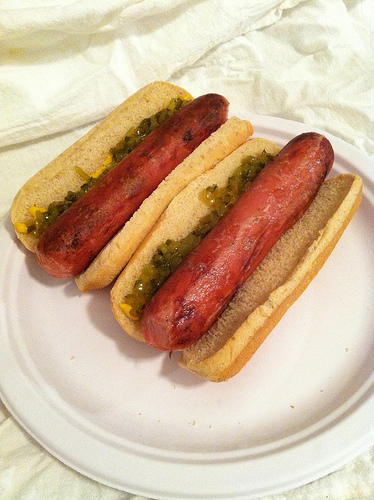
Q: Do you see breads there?
A: Yes, there is a bread.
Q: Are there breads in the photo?
A: Yes, there is a bread.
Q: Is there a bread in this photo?
A: Yes, there is a bread.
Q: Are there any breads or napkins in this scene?
A: Yes, there is a bread.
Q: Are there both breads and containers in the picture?
A: No, there is a bread but no containers.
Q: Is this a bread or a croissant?
A: This is a bread.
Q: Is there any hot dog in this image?
A: Yes, there is a hot dog.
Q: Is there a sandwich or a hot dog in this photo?
A: Yes, there is a hot dog.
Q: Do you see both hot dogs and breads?
A: Yes, there are both a hot dog and a bread.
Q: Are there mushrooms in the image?
A: No, there are no mushrooms.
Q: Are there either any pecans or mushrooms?
A: No, there are no mushrooms or pecans.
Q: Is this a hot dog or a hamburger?
A: This is a hot dog.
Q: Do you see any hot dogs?
A: Yes, there is a hot dog.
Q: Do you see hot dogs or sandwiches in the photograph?
A: Yes, there is a hot dog.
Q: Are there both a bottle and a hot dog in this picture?
A: No, there is a hot dog but no bottles.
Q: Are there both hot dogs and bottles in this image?
A: No, there is a hot dog but no bottles.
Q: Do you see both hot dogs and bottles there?
A: No, there is a hot dog but no bottles.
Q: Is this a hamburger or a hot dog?
A: This is a hot dog.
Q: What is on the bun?
A: The hot dog is on the bun.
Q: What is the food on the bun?
A: The food is a hot dog.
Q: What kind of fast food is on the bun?
A: The food is a hot dog.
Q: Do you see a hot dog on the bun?
A: Yes, there is a hot dog on the bun.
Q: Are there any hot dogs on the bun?
A: Yes, there is a hot dog on the bun.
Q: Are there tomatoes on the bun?
A: No, there is a hot dog on the bun.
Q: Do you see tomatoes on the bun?
A: No, there is a hot dog on the bun.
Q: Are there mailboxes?
A: No, there are no mailboxes.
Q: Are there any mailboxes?
A: No, there are no mailboxes.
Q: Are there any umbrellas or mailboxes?
A: No, there are no mailboxes or umbrellas.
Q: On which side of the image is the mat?
A: The mat is on the left of the image.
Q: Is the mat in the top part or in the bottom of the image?
A: The mat is in the bottom of the image.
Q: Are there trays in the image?
A: No, there are no trays.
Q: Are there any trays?
A: No, there are no trays.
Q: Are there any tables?
A: Yes, there is a table.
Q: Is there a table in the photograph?
A: Yes, there is a table.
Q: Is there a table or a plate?
A: Yes, there is a table.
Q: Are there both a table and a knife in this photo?
A: No, there is a table but no knives.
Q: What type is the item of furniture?
A: The piece of furniture is a table.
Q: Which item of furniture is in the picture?
A: The piece of furniture is a table.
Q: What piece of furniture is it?
A: The piece of furniture is a table.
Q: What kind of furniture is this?
A: That is a table.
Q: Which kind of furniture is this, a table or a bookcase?
A: That is a table.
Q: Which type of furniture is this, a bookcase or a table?
A: That is a table.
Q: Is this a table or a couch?
A: This is a table.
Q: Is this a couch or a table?
A: This is a table.